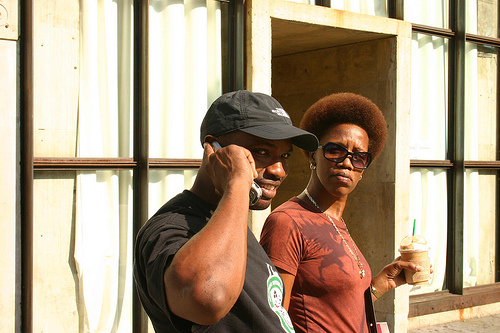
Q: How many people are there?
A: Two.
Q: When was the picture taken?
A: Daytime.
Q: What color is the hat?
A: Black.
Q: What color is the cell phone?
A: Gray.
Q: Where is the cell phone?
A: In the man's hand.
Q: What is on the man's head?
A: A hat.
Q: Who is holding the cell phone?
A: The man.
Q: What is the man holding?
A: A cell phone.